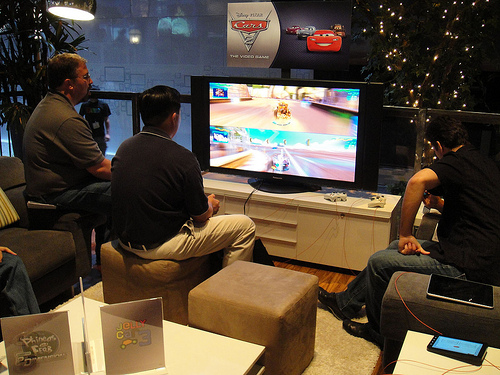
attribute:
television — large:
[182, 68, 381, 198]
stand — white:
[195, 165, 438, 280]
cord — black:
[233, 172, 261, 232]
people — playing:
[14, 35, 484, 341]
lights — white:
[368, 4, 473, 143]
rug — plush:
[86, 249, 373, 372]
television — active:
[173, 60, 381, 191]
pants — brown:
[126, 213, 254, 287]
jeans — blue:
[0, 244, 51, 324]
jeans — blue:
[332, 238, 466, 318]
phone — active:
[404, 308, 484, 369]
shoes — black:
[311, 278, 389, 354]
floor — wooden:
[166, 237, 416, 322]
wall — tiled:
[8, 4, 482, 194]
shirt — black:
[107, 131, 216, 247]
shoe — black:
[311, 269, 385, 348]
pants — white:
[95, 216, 268, 293]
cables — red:
[407, 305, 441, 340]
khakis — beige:
[162, 199, 275, 289]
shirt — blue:
[104, 139, 207, 237]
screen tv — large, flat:
[171, 65, 384, 215]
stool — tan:
[91, 230, 202, 325]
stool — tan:
[200, 257, 321, 362]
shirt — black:
[97, 120, 197, 220]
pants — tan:
[113, 204, 319, 300]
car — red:
[303, 28, 352, 66]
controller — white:
[322, 180, 358, 219]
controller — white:
[363, 188, 393, 213]